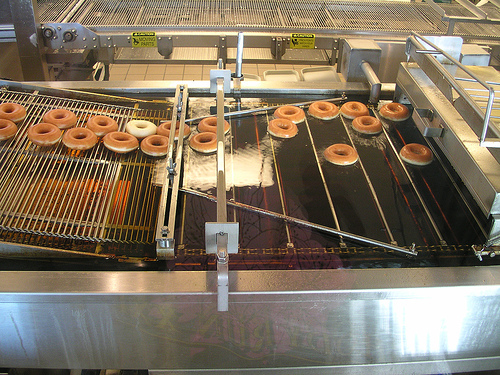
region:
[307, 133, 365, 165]
this is a donut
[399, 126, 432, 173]
this is a donut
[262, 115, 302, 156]
this is a donut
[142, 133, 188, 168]
this is a donut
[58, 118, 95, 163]
this is a donut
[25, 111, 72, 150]
this is a donut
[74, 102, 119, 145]
this is a donut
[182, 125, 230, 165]
this is a donut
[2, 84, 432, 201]
donuts on food conveyer belt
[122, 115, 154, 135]
one uncooked donut on conveyor belt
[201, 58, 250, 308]
metal rod across conveyor belt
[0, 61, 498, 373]
large metal machinery in kitchen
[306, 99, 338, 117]
bron top of partially cooked donut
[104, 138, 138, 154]
white center of donut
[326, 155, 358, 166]
white bottom of partially cooked donut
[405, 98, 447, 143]
handle on metal machinery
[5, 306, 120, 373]
drip marks on side of machinery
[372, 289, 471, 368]
light reflecting on side of machinery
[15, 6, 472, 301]
inside a donut-making facility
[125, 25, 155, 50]
warning label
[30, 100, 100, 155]
four donuts move on the grill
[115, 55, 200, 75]
brown, square tiles on the floor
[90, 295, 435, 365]
reflection in the metal surface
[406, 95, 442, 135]
handle of the metal mechanism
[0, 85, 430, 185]
donuts being prepared by machine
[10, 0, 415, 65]
unused portion of the machine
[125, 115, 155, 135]
not-fully-cooked donut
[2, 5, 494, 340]
donut-making machinery in action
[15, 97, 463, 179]
Donuts are on the conveyor belt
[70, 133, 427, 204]
Grease is underneath the donuts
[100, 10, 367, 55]
The back conveyor belt is empty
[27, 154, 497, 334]
The conveyor belt is made of steel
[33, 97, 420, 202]
The donuts are going into the grease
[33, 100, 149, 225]
The conveyor belt is hot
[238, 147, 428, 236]
Grease is underneath the conveyor belt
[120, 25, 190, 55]
A yellow warning sign is on the equipment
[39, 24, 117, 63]
Two knobs are on the machine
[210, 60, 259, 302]
A pole is over the conveyor belt